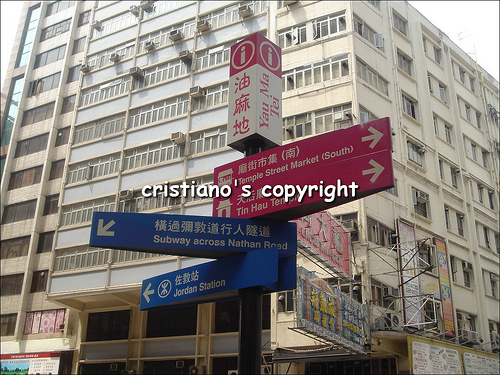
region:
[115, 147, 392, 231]
letters on the picture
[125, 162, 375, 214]
the letters are white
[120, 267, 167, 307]
the arrow is pointing left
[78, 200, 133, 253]
the arrow is pointing down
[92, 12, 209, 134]
air conditioners in the windows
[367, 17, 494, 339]
the building is cream colored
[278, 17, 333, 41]
the windows are open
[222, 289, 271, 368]
the pole is black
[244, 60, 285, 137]
the letters are red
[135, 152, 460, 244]
a text in the pic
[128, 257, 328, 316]
a board in top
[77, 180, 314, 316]
two boards in top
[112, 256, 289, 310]
a blue board indicating adress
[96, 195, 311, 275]
a sign with a white arrow pointing down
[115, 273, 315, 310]
blue sign with an arrow pointing to the left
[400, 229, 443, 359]
empty sign holders on the side of the building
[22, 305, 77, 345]
red and white covering on the windows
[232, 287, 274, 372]
a black pole holding all the signs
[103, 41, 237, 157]
air conditioner in windows on the building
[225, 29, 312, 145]
a red and white sign with a big "i" in white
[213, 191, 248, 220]
a red and white sign with a house in white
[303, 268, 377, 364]
signs in metal frames on side of building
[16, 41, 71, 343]
white pipe going up the building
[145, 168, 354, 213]
This says "cristiano's copyright"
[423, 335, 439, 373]
This has a white sign on it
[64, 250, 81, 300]
There are windows here that are visible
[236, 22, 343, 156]
There is a red sign visible here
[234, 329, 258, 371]
There is a black pole here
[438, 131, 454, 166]
There is a window that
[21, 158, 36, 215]
There is some off-white concrete here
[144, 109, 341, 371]
Jackson Mingus took this photo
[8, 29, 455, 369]
this is an urban setting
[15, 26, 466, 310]
this is in a city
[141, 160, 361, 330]
this is a street corner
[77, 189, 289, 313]
these signs are blue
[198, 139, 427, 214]
these signs are pink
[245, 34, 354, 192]
this sign is white and pink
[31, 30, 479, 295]
this is a tall building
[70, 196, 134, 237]
this arrow is pointing down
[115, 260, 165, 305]
this arrow is pointing left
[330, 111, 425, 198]
this arrow is pointing right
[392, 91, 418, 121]
the window of a building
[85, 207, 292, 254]
blue sign on the on the pole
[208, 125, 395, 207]
red sign on the on the pole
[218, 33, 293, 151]
red and white sign on the on the pole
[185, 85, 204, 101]
air conditioner in the window